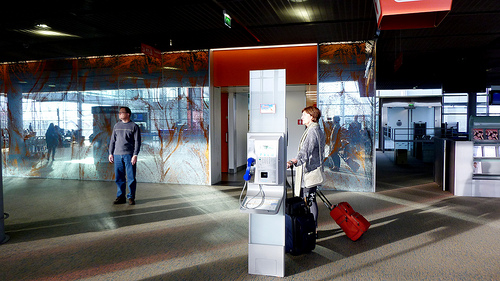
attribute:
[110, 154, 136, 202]
jeans — blue, pair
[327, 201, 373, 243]
luggage — red, orange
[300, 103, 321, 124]
hair — short, brown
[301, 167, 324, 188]
purse — white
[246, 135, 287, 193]
pay phone — white, large, blue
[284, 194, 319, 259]
suitcase — black, blue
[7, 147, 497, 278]
floor — gray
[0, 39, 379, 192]
wall — glass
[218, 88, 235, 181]
door — orange, red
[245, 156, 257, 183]
handset — blue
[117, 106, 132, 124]
hair — black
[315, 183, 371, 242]
suitcase — red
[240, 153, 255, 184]
handle — blue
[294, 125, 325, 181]
sweater — gray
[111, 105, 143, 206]
man — standing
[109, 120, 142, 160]
sweater — gray, long sleeved